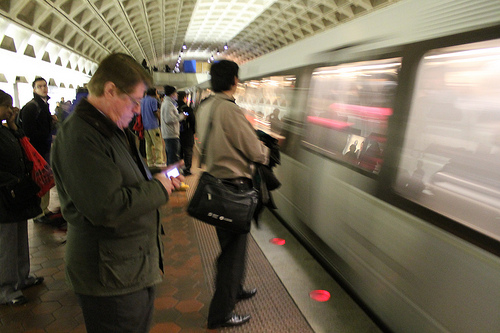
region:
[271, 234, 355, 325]
red circle lights on ground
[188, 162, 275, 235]
leather black shoulder bag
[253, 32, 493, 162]
moving train car in motion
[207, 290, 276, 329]
black shiny men's shoes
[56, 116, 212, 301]
dark green rain jacket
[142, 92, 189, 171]
man wearing a blue shirt and khaki pants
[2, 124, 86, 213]
red and black tote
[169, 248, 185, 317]
red and brown shaped tile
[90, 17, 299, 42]
geometric shaped ceiling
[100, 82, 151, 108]
man with older glasses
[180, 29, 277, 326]
a person is standing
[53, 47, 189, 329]
a person is standing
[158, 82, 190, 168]
a person is standing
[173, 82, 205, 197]
a person is standing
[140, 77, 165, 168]
a person is standing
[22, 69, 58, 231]
a person is standing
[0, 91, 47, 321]
a person is standing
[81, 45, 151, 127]
the head of a person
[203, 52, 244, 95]
the head of a person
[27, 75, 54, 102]
the head of a person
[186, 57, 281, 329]
man holding black shoulder bag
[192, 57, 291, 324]
man standing near train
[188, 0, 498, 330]
train is moving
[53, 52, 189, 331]
man looking at his cellphone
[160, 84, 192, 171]
person wearing black hat standing on platform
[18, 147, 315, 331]
floor of platform is tile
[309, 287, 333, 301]
red lights on platform near train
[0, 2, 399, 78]
ceiling of subway is coffered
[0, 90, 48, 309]
person holding red bag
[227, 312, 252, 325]
man wearing shiny black dress shoes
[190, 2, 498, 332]
subway train is moving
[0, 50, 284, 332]
people are waiting for train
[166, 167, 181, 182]
person looking at his phone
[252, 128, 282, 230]
man holding black coat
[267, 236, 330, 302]
two red lights under train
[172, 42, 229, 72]
lights on ceiling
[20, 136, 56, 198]
woman carrying red bag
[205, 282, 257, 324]
man wearing leather shoes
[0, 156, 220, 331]
floor is brown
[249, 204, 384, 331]
gray strip next to train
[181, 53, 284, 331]
Man stand in a train station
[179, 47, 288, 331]
Man carry a bag on right shoulder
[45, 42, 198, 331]
Man is blonde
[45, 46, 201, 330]
Man is looking a cell phone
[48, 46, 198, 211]
Man has cell phone on left hand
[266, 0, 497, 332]
Train is in motion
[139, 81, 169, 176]
Man wears a blue shirt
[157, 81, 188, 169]
Man wears a black hat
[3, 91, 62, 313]
Woman holding a red bag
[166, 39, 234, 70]
White lights on ceiling